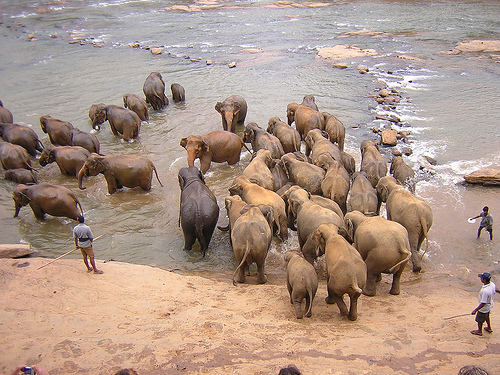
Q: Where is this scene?
A: Waterbody.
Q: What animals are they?
A: Elephants.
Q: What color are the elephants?
A: Brown.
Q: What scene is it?
A: Outdoor.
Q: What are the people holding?
A: Canes.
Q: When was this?
A: Daytime.